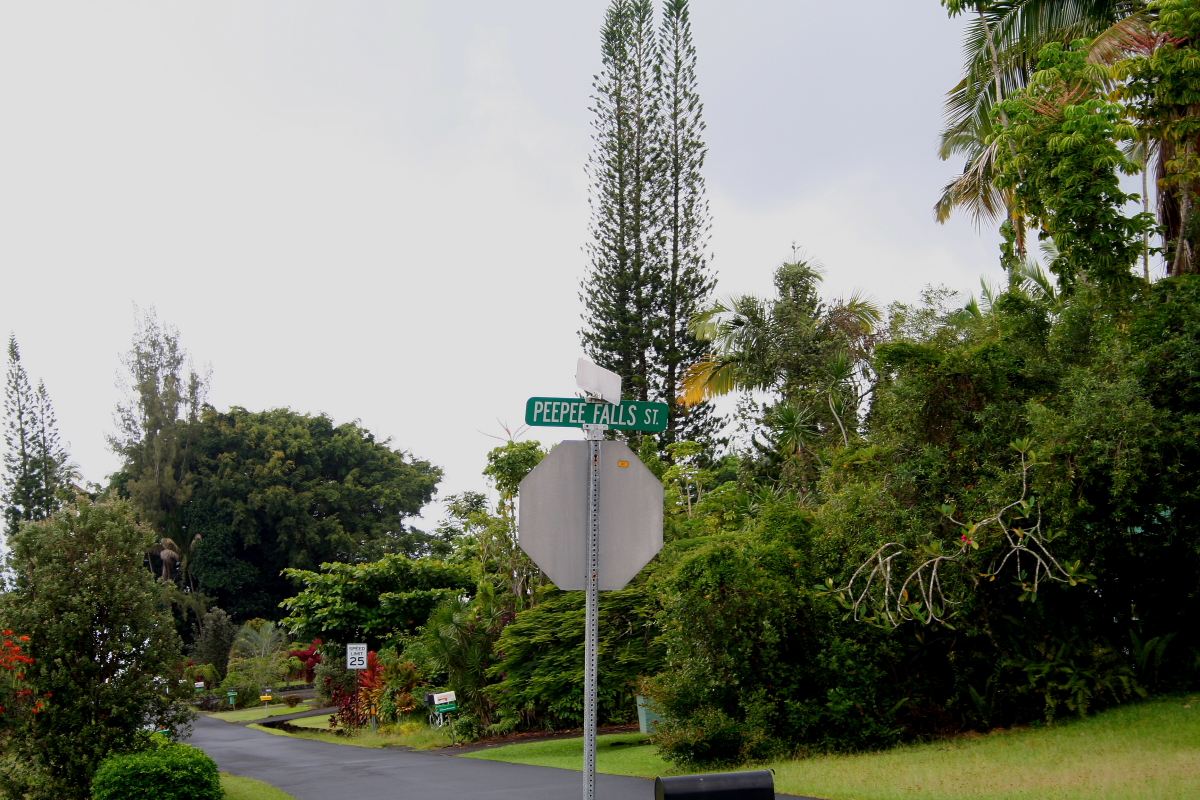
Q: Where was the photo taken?
A: Peepee Falls Street.